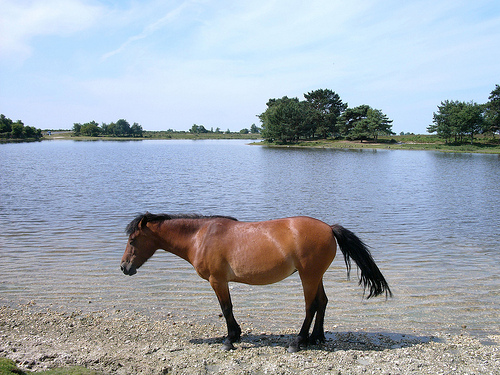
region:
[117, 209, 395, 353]
Small, brown horse standing near a lake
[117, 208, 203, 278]
Head of a small, brown horse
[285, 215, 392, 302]
Rear end of a horse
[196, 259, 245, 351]
Front leg of a small horse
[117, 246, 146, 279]
Snout of a brown horse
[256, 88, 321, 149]
Trees standing near a lake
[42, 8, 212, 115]
Blue sky filled with thin clouds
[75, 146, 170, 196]
Clear water of a lake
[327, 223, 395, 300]
Black tail of a horse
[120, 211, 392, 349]
A horse standing next to water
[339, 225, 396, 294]
tail of the horse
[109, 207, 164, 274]
head of the horse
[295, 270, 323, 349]
back legs of the horse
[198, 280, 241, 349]
front legs of the horse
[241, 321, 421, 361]
shadow of the horse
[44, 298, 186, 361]
stones on the ground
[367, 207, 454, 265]
water on the ground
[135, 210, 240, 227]
mane of the horse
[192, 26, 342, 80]
clouds in the sky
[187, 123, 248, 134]
trees on the grass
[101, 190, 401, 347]
A horse in the photo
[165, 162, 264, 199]
Water in the photo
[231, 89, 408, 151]
A tree in the photo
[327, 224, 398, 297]
A horse tail in the photo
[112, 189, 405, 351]
A brown horse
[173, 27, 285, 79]
clouds in the photo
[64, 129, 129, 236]
River in the photo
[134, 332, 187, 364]
mud on the riverbank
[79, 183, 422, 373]
a horse in the ground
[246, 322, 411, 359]
shadow on the ground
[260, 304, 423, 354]
shadow of the horse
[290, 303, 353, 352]
back legs of the horse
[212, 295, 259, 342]
front legs of horse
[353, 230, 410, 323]
tail of the horse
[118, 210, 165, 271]
face of the horse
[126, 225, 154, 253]
eye of the horse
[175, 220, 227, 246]
brown skin of horse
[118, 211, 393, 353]
brown horse with black tail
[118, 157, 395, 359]
horse standing near lake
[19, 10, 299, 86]
light blue sky with some clouds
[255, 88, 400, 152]
group of trees on shore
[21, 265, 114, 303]
small ripples in water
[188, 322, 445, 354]
shadow of horse on shore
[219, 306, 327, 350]
black hooves of a horse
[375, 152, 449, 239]
light reflecting on water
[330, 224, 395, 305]
black tail of a horse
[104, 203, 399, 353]
A brown horse.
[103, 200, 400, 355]
The horse stands on the shore.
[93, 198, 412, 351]
A horse walking at the edge of the water.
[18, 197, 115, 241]
Small ripples on the water.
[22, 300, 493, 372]
A grey rocky shore.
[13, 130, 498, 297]
A body of water behind the horse.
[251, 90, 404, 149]
Trees on the island.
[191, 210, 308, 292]
The sun shining on the horse's fur.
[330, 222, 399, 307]
The black tail of the horse.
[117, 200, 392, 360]
The brown horse stands close to the water.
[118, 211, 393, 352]
a brown horse standing near the water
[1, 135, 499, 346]
the large body of water behind the horse